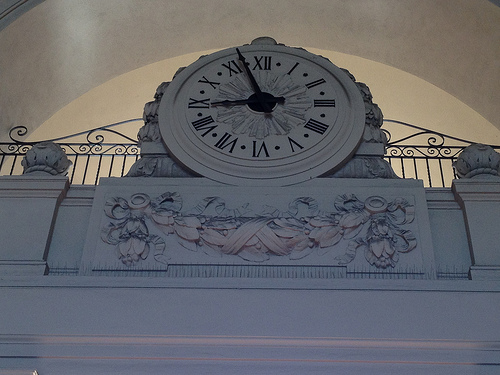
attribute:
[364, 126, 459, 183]
rail — black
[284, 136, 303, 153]
roman numeral — black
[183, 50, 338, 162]
face — white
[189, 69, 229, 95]
numeral — black, roman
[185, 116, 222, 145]
numeral — roman, black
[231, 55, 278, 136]
hands — black